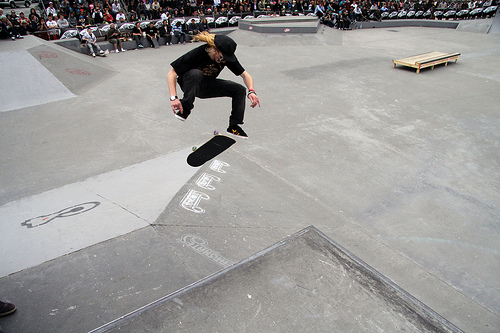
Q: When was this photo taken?
A: Daytime.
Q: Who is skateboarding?
A: A male.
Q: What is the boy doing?
A: Skateboarding.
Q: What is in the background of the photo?
A: Spectators.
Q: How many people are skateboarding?
A: One.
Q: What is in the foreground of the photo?
A: A person skateboarding.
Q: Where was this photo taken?
A: At a skateboard park in a city.